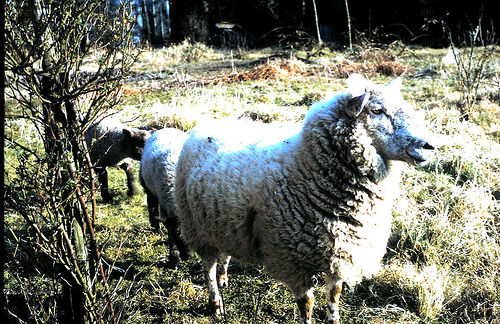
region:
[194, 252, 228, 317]
white leg on sheep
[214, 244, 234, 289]
white leg on sheep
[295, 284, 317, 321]
white leg on sheep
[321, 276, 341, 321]
white leg on sheep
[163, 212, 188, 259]
black leg on sheep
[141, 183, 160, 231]
black leg on sheep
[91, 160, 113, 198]
black leg on sheep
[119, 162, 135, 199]
black leg on sheep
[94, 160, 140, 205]
black legs on sheep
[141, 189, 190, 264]
black legs on sheep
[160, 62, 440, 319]
A sheep in a grassy field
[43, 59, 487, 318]
several sheep in a pasture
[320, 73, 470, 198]
the head of a sheep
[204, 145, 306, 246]
the wool of a sheep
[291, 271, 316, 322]
the leg of a sheep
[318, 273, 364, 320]
the leg of a sheep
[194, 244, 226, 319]
the leg of a sheep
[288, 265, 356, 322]
the front legs of a sheep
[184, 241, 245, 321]
the rear legs of a sheep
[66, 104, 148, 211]
a small black lamb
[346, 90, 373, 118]
the ear of a sheep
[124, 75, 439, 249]
a sheep is in the grass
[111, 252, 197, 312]
the grass is dead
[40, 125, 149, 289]
the leaves have no branches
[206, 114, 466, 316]
the sheep is dirty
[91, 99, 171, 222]
a cat is behind the lamb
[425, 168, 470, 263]
the grass is overgrown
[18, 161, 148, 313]
there are multiple branches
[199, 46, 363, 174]
the grass is by the log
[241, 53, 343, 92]
the moss is brown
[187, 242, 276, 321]
the lamb has thin legs